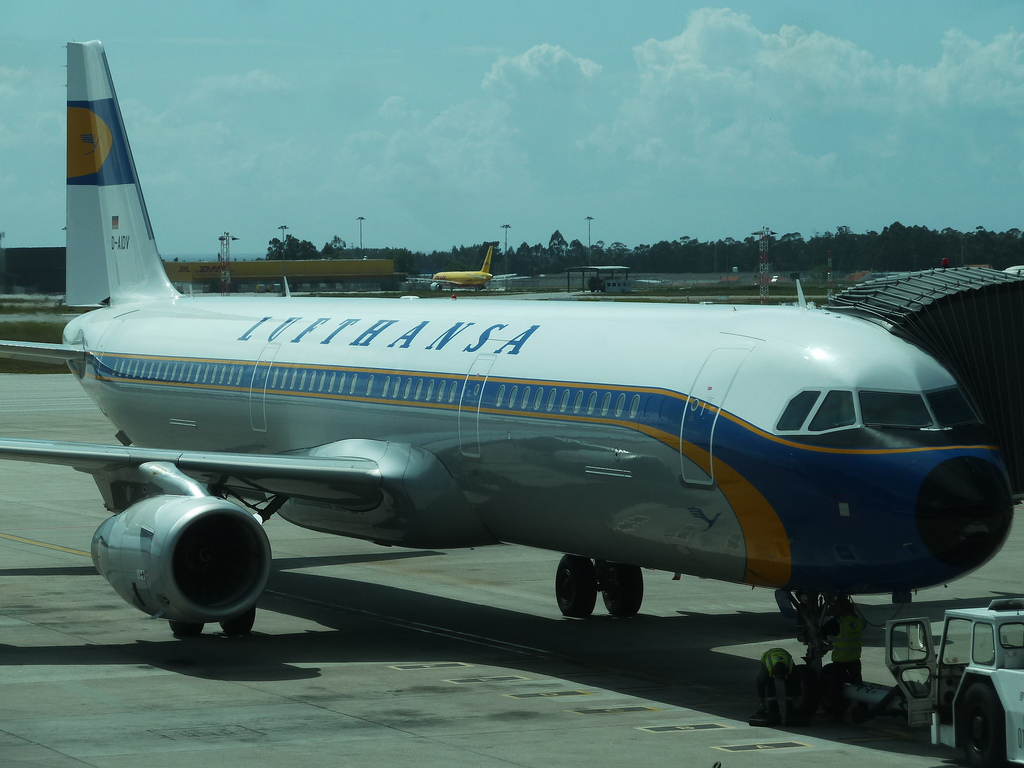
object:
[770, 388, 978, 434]
windows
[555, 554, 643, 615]
wheels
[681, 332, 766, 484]
door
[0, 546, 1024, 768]
shadow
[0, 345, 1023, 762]
runway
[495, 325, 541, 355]
letter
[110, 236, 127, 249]
letter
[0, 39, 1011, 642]
airplane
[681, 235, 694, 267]
tree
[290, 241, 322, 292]
tree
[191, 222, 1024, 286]
woods